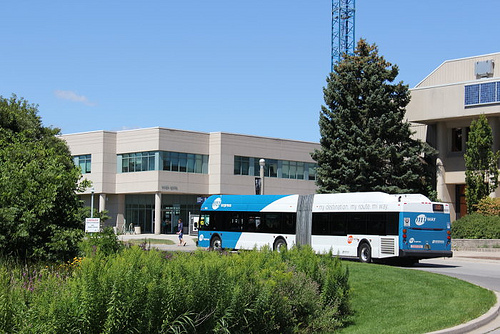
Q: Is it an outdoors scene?
A: Yes, it is outdoors.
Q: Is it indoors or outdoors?
A: It is outdoors.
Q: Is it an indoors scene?
A: No, it is outdoors.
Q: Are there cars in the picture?
A: No, there are no cars.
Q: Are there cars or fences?
A: No, there are no cars or fences.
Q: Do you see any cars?
A: No, there are no cars.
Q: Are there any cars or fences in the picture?
A: No, there are no cars or fences.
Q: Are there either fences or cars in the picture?
A: No, there are no cars or fences.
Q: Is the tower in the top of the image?
A: Yes, the tower is in the top of the image.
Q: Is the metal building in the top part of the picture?
A: Yes, the tower is in the top of the image.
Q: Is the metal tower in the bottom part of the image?
A: No, the tower is in the top of the image.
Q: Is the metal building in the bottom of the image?
A: No, the tower is in the top of the image.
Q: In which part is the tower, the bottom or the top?
A: The tower is in the top of the image.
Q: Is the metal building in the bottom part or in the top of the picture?
A: The tower is in the top of the image.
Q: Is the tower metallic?
A: Yes, the tower is metallic.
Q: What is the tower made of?
A: The tower is made of metal.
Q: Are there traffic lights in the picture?
A: No, there are no traffic lights.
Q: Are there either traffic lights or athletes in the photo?
A: No, there are no traffic lights or athletes.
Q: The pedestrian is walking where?
A: The pedestrian is walking on the sidewalk.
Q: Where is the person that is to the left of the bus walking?
A: The pedestrian is walking on the sidewalk.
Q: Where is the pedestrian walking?
A: The pedestrian is walking on the sidewalk.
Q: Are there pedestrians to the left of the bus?
A: Yes, there is a pedestrian to the left of the bus.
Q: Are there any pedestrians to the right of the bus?
A: No, the pedestrian is to the left of the bus.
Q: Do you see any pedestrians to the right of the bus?
A: No, the pedestrian is to the left of the bus.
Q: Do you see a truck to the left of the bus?
A: No, there is a pedestrian to the left of the bus.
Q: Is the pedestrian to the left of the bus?
A: Yes, the pedestrian is to the left of the bus.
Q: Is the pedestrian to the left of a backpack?
A: No, the pedestrian is to the left of the bus.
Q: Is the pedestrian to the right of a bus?
A: No, the pedestrian is to the left of a bus.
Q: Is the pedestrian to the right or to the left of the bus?
A: The pedestrian is to the left of the bus.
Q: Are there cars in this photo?
A: No, there are no cars.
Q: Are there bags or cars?
A: No, there are no cars or bags.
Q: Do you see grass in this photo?
A: Yes, there is grass.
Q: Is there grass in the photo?
A: Yes, there is grass.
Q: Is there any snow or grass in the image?
A: Yes, there is grass.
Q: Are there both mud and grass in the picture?
A: No, there is grass but no mud.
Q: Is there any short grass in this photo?
A: Yes, there is short grass.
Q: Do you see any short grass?
A: Yes, there is short grass.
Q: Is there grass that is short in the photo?
A: Yes, there is short grass.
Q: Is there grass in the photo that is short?
A: Yes, there is grass that is short.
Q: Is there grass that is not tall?
A: Yes, there is short grass.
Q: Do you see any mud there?
A: No, there is no mud.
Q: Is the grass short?
A: Yes, the grass is short.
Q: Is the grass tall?
A: No, the grass is short.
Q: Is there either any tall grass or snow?
A: No, there is grass but it is short.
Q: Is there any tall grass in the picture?
A: No, there is grass but it is short.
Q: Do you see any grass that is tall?
A: No, there is grass but it is short.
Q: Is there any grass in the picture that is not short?
A: No, there is grass but it is short.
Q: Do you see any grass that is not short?
A: No, there is grass but it is short.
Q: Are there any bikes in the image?
A: No, there are no bikes.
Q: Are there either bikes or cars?
A: No, there are no bikes or cars.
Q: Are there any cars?
A: No, there are no cars.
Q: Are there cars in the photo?
A: No, there are no cars.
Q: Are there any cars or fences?
A: No, there are no cars or fences.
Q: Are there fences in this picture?
A: No, there are no fences.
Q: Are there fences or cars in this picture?
A: No, there are no cars or fences.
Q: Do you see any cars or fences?
A: No, there are no cars or fences.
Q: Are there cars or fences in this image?
A: No, there are no cars or fences.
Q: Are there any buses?
A: Yes, there is a bus.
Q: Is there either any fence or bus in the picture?
A: Yes, there is a bus.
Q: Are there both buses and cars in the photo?
A: No, there is a bus but no cars.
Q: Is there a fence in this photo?
A: No, there are no fences.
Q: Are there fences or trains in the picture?
A: No, there are no fences or trains.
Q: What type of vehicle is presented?
A: The vehicle is a bus.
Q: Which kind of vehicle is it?
A: The vehicle is a bus.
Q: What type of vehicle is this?
A: This is a bus.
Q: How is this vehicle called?
A: This is a bus.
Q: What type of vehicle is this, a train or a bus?
A: This is a bus.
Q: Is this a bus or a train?
A: This is a bus.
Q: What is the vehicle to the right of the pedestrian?
A: The vehicle is a bus.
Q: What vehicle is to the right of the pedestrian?
A: The vehicle is a bus.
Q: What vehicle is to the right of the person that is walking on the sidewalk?
A: The vehicle is a bus.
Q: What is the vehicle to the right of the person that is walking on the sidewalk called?
A: The vehicle is a bus.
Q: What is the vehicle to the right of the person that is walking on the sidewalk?
A: The vehicle is a bus.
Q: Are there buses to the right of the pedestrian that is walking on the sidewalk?
A: Yes, there is a bus to the right of the pedestrian.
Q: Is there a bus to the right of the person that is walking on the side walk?
A: Yes, there is a bus to the right of the pedestrian.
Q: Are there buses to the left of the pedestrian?
A: No, the bus is to the right of the pedestrian.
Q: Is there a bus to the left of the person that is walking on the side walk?
A: No, the bus is to the right of the pedestrian.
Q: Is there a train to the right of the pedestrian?
A: No, there is a bus to the right of the pedestrian.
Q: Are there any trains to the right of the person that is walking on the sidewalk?
A: No, there is a bus to the right of the pedestrian.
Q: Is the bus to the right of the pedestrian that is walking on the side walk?
A: Yes, the bus is to the right of the pedestrian.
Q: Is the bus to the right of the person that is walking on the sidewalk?
A: Yes, the bus is to the right of the pedestrian.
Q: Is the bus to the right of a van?
A: No, the bus is to the right of the pedestrian.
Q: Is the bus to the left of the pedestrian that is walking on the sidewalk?
A: No, the bus is to the right of the pedestrian.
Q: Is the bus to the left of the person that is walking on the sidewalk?
A: No, the bus is to the right of the pedestrian.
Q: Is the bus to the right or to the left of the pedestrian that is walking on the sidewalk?
A: The bus is to the right of the pedestrian.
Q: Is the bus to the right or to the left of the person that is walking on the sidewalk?
A: The bus is to the right of the pedestrian.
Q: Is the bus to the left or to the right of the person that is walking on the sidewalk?
A: The bus is to the right of the pedestrian.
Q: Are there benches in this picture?
A: No, there are no benches.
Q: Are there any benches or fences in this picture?
A: No, there are no benches or fences.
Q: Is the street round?
A: Yes, the street is round.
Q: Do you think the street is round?
A: Yes, the street is round.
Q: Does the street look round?
A: Yes, the street is round.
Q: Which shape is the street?
A: The street is round.